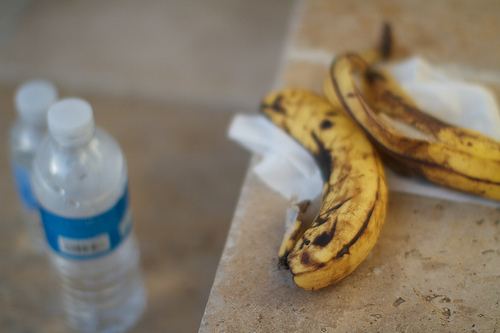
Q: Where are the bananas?
A: On the table.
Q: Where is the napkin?
A: Under the bananas.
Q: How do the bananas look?
A: Rotten.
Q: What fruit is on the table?
A: Bananas.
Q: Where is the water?
A: Left of the table.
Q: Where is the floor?
A: Under the water bottles.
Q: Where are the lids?
A: On the water bottles.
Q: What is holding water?
A: The bottles.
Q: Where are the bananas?
A: On table.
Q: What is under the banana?
A: Napkin.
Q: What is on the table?
A: Bananas.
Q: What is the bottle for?
A: Water.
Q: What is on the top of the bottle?
A: Lid.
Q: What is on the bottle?
A: Label.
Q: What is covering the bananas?
A: Bruises.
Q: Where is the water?
A: On the table.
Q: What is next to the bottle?
A: Another bottle.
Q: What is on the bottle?
A: Label.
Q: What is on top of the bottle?
A: Lid.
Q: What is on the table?
A: Bananas.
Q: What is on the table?
A: Napkin.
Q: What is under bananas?
A: Napkin.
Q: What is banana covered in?
A: Bruises.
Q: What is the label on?
A: Water.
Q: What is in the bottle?
A: Water.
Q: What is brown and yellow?
A: Bananas.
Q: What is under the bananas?
A: Napkin.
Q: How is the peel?
A: Split.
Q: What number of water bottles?
A: Two.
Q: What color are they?
A: Yellow.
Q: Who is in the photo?
A: No one.